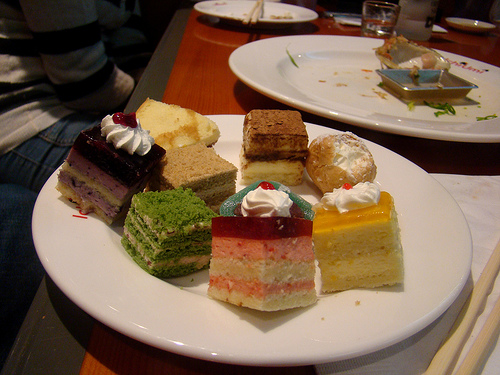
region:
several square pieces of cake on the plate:
[65, 90, 423, 327]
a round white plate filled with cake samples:
[41, 93, 446, 372]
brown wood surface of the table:
[97, 345, 143, 372]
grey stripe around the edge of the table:
[146, 7, 193, 81]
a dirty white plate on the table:
[272, 21, 489, 147]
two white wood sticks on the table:
[413, 210, 499, 373]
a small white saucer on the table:
[443, 10, 498, 39]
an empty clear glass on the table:
[353, 3, 401, 42]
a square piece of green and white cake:
[121, 184, 213, 285]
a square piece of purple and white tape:
[58, 111, 135, 233]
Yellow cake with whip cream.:
[316, 184, 414, 297]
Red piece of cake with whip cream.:
[226, 179, 318, 320]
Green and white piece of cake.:
[126, 185, 211, 272]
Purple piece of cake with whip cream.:
[66, 120, 126, 224]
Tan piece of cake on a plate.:
[177, 143, 242, 192]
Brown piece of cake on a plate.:
[243, 106, 308, 180]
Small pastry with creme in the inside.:
[318, 130, 380, 178]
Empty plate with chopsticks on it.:
[197, 1, 342, 26]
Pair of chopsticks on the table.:
[439, 218, 496, 364]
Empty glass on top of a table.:
[351, 1, 403, 45]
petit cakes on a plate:
[36, 86, 472, 357]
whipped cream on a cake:
[243, 177, 295, 223]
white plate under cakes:
[401, 181, 463, 328]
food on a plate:
[271, 28, 498, 138]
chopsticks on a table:
[423, 231, 492, 373]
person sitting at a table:
[6, 7, 129, 200]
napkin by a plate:
[453, 169, 494, 244]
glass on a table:
[358, 1, 403, 36]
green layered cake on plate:
[129, 183, 205, 270]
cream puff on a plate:
[311, 123, 379, 192]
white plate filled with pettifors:
[36, 90, 411, 325]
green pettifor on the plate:
[122, 185, 212, 278]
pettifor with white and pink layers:
[202, 180, 322, 315]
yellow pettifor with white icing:
[313, 172, 413, 295]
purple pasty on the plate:
[54, 111, 173, 228]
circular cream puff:
[309, 130, 377, 186]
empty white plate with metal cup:
[239, 35, 499, 155]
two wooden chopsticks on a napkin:
[424, 193, 498, 373]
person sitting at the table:
[0, 0, 141, 210]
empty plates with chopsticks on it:
[192, 1, 320, 33]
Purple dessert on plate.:
[86, 129, 124, 214]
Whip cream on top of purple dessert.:
[106, 119, 145, 154]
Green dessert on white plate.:
[126, 198, 200, 300]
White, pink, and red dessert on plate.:
[216, 215, 291, 328]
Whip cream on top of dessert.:
[238, 185, 279, 219]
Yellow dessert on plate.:
[324, 205, 395, 284]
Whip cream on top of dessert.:
[340, 185, 372, 211]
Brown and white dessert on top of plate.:
[323, 135, 361, 174]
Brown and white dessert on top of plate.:
[250, 118, 300, 192]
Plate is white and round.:
[98, 85, 395, 374]